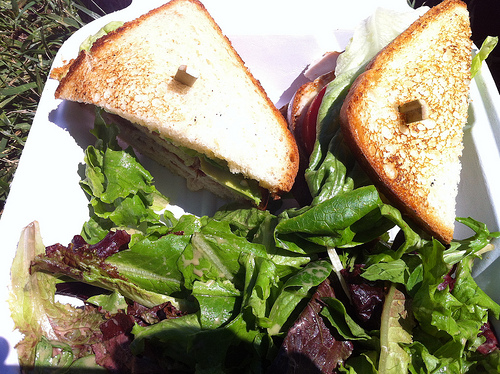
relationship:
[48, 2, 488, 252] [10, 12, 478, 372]
bread in dish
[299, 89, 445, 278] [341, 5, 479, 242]
lettuce on bread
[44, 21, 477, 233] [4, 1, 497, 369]
food on plate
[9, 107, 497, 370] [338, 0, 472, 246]
lettuce next to bread